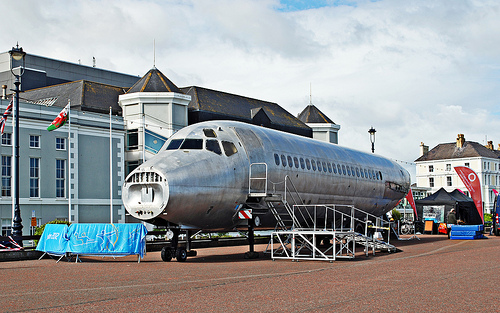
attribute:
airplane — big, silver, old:
[120, 120, 410, 262]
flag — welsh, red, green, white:
[45, 99, 72, 132]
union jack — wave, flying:
[0, 95, 17, 138]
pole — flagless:
[108, 105, 113, 225]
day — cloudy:
[1, 2, 499, 172]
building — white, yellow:
[417, 137, 499, 214]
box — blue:
[450, 222, 483, 229]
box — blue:
[449, 230, 481, 237]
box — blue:
[447, 234, 481, 241]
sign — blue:
[35, 221, 144, 257]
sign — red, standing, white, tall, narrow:
[453, 164, 483, 227]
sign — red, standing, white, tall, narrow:
[398, 191, 421, 220]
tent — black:
[416, 189, 480, 230]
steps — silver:
[246, 186, 301, 233]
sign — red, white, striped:
[237, 205, 255, 221]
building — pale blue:
[2, 48, 339, 248]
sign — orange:
[423, 216, 435, 233]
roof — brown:
[413, 141, 499, 159]